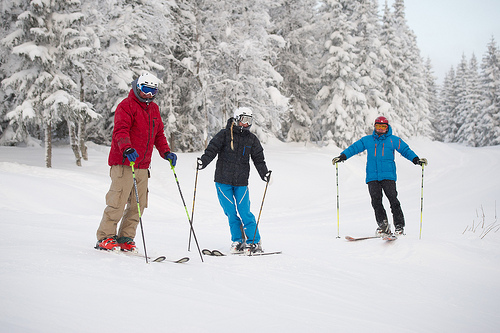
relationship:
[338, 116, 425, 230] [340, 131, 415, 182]
person wears coat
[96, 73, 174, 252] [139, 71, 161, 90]
man wears helmet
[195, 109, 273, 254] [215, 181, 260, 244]
woman wears pants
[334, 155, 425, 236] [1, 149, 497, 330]
skis in snow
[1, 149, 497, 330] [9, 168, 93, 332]
snow on ground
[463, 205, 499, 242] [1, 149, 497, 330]
weeds in snow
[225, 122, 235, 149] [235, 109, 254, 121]
braid under helmet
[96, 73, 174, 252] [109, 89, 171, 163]
man wears coat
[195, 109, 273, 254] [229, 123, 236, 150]
woman has hair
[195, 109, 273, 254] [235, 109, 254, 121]
woman wears helmet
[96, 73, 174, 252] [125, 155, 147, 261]
man holds pole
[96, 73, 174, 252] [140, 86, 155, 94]
man wears goggles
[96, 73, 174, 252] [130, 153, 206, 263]
man has skis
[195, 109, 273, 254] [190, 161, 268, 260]
woman has skis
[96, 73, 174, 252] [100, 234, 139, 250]
man wears ski shoes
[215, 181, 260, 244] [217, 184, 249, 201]
pants have stripe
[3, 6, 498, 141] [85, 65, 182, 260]
trees behind man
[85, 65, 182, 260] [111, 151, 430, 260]
man holding poles